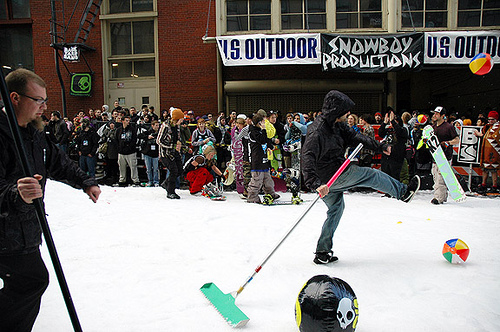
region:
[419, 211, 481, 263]
the ball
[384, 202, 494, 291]
the ball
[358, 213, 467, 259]
the ball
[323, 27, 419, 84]
The sign is black with white letters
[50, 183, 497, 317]
the ground is covered in snow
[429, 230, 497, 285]
the beach ball has many different colors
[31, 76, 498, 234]
a crowd of people are watching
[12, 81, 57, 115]
the man is wearing glasses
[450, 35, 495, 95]
a beach ball is in the air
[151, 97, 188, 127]
the man is wearing an orange hat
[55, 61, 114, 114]
the sign is green and black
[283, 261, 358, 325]
the ball is black with white skulls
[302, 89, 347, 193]
the man's jacket is black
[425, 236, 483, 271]
beach ball on the snow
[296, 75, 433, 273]
man with one foot in the air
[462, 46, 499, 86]
colorful beach ball in the sky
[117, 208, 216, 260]
white snow on the ground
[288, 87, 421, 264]
man wearing a black jacket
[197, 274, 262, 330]
teal shovel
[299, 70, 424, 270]
man holding a shovel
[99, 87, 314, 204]
crowd standing next to a building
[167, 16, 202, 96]
red brick building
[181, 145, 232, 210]
man wearing red pants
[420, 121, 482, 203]
man holding a snowboard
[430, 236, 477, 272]
a beach ball in the snow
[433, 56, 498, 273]
two beach balls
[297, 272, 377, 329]
skull on a black ball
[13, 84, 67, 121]
man wearing glasses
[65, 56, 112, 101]
skull sign is green and black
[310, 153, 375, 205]
pink tape on the shovel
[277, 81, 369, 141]
man has his hood up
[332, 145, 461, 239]
man is kicking his leg up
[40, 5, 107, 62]
emergency ladder on the building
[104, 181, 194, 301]
the snow is white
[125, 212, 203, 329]
the snow is white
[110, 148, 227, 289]
the snow is white